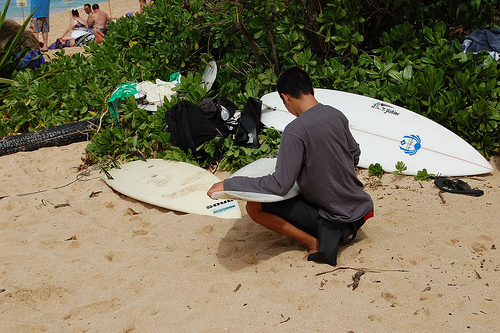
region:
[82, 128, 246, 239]
white surfboard in sand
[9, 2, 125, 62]
people sitting on the beach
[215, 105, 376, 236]
grey long sleeve shirt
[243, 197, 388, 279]
tied up black wetsuit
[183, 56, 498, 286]
man kneeling near surfboards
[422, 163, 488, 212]
black safety strap for surfboard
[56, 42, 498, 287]
man kneels near surfing equipment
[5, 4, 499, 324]
man kneeling in the sand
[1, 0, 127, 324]
people enjoying the beach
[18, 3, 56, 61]
man in blue shirt on beach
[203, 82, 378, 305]
person holding surfboard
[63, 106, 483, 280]
three surboards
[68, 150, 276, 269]
surfboard is in the sand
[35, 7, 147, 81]
people sitting in the sand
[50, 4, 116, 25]
water is blue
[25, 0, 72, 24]
man is wearing a blue shirt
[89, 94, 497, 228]
three surfboards are white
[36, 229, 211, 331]
sand is tan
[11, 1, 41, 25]
sign on the beach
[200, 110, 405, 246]
man is wearing a long sleeve shirt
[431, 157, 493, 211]
one pair of black slipper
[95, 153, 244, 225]
The board on the sand in front of the man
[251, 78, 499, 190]
The board to the right of the man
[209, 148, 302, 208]
The board the man is holding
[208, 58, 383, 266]
The man squatting on the sand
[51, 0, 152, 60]
The people sitting on the beach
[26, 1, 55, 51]
The man in the blue shirt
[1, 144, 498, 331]
The sand beneath the man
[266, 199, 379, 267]
The man's black shorts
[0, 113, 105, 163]
The burnt log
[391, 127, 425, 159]
The blue sticker on the board to the right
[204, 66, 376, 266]
a young man squatting on the sand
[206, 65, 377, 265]
a boy holding a white surfboard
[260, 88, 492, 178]
a white surfboard leaning against the bushes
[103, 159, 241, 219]
a white surfboard on the sand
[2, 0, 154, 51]
people sitting and standing on the sand at the beach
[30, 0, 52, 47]
a man in a blue t-shirt standing on the beach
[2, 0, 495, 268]
men and women at the beach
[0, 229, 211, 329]
sand on the ground at the beach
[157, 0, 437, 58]
bushes with green leaves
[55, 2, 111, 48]
three people sitting on the beach in front of the water